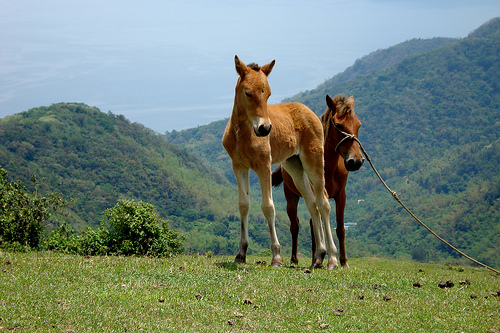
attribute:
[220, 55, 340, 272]
pony — dark, brown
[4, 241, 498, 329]
grass — green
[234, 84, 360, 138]
eyes — slanted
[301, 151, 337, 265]
legs — white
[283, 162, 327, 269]
legs — white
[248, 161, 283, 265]
legs — white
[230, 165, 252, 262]
legs — white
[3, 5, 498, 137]
sky — blue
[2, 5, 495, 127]
clouds — thin, whispy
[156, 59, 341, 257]
colt — brown and white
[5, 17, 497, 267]
range — mountainous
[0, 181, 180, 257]
bushes — Small 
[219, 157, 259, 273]
leg — white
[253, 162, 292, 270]
leg — white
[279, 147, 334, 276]
leg — white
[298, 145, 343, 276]
leg — white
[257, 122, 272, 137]
nose — black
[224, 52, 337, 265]
horse — brown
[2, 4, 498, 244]
hills — green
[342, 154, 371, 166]
nose — black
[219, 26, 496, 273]
forest — thick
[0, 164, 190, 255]
bushes — small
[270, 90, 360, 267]
horse — brown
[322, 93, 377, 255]
horse — brown, baby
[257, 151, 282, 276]
leg — long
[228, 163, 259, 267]
leg — long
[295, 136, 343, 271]
leg — long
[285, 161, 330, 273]
leg — long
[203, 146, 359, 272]
legs — light brown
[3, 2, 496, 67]
sky — fair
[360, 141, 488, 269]
rope — long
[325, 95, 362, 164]
head — horse's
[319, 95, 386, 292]
horse — baby